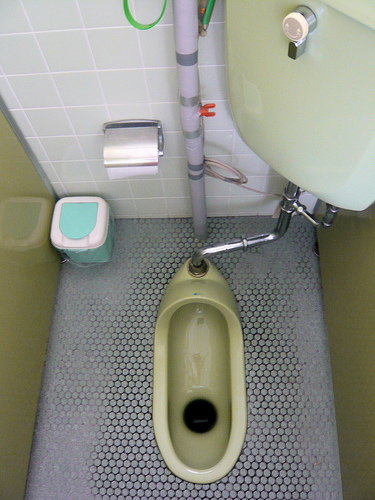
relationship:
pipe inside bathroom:
[170, 0, 209, 240] [1, 1, 372, 498]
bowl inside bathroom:
[152, 256, 246, 485] [0, 0, 375, 500]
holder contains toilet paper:
[97, 116, 166, 169] [108, 166, 157, 178]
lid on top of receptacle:
[49, 195, 107, 249] [49, 195, 116, 264]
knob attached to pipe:
[198, 103, 214, 118] [170, 0, 209, 240]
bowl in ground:
[152, 256, 246, 485] [24, 211, 344, 498]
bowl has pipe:
[154, 256, 245, 481] [170, 0, 209, 240]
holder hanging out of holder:
[101, 116, 164, 183] [101, 116, 164, 183]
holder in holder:
[101, 116, 164, 183] [101, 116, 164, 183]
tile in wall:
[20, 3, 91, 34] [3, 2, 369, 227]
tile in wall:
[84, 25, 145, 78] [3, 2, 369, 227]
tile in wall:
[51, 158, 96, 189] [3, 2, 369, 227]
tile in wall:
[20, 100, 80, 149] [3, 2, 369, 227]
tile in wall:
[94, 64, 157, 113] [3, 2, 369, 227]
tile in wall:
[124, 177, 170, 203] [0, 2, 318, 216]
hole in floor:
[172, 384, 234, 451] [21, 210, 346, 498]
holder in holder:
[101, 116, 164, 183] [105, 123, 161, 168]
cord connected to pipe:
[200, 156, 290, 202] [187, 181, 304, 347]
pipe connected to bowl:
[187, 181, 304, 347] [152, 256, 246, 485]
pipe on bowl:
[187, 187, 294, 264] [152, 256, 246, 485]